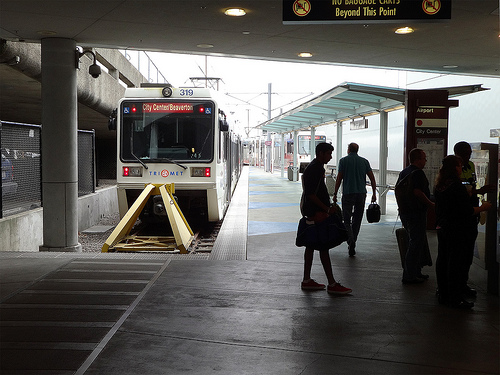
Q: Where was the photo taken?
A: It was taken at the airport.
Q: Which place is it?
A: It is an airport.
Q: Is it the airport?
A: Yes, it is the airport.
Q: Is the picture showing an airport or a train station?
A: It is showing an airport.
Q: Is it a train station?
A: No, it is an airport.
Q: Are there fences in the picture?
A: Yes, there is a fence.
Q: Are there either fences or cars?
A: Yes, there is a fence.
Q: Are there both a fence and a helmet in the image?
A: No, there is a fence but no helmets.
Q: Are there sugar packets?
A: No, there are no sugar packets.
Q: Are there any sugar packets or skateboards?
A: No, there are no sugar packets or skateboards.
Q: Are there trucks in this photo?
A: No, there are no trucks.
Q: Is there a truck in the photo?
A: No, there are no trucks.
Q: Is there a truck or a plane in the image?
A: No, there are no trucks or airplanes.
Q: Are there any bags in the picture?
A: Yes, there is a bag.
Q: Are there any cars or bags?
A: Yes, there is a bag.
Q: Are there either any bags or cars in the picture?
A: Yes, there is a bag.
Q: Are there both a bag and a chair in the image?
A: No, there is a bag but no chairs.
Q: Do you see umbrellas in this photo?
A: No, there are no umbrellas.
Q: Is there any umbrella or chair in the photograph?
A: No, there are no umbrellas or chairs.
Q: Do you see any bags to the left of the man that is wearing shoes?
A: Yes, there is a bag to the left of the man.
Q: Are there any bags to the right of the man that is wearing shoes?
A: No, the bag is to the left of the man.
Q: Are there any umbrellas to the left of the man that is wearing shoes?
A: No, there is a bag to the left of the man.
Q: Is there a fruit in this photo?
A: No, there are no fruits.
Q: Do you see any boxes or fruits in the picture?
A: No, there are no fruits or boxes.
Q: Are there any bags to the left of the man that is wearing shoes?
A: Yes, there are bags to the left of the man.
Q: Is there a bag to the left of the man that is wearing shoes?
A: Yes, there are bags to the left of the man.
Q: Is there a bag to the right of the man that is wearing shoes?
A: No, the bags are to the left of the man.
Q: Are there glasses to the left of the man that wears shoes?
A: No, there are bags to the left of the man.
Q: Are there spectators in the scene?
A: No, there are no spectators.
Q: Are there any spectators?
A: No, there are no spectators.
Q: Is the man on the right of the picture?
A: Yes, the man is on the right of the image.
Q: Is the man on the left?
A: No, the man is on the right of the image.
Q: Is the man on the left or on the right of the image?
A: The man is on the right of the image.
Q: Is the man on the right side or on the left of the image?
A: The man is on the right of the image.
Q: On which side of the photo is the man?
A: The man is on the right of the image.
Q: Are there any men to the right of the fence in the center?
A: Yes, there is a man to the right of the fence.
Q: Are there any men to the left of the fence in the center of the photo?
A: No, the man is to the right of the fence.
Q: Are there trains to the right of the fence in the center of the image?
A: No, there is a man to the right of the fence.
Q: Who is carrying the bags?
A: The man is carrying the bags.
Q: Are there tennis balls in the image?
A: No, there are no tennis balls.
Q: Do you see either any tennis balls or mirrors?
A: No, there are no tennis balls or mirrors.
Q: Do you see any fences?
A: Yes, there is a fence.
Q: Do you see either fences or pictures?
A: Yes, there is a fence.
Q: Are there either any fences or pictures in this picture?
A: Yes, there is a fence.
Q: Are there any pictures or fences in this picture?
A: Yes, there is a fence.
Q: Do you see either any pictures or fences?
A: Yes, there is a fence.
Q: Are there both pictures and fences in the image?
A: No, there is a fence but no pictures.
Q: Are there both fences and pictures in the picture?
A: No, there is a fence but no pictures.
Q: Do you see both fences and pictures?
A: No, there is a fence but no pictures.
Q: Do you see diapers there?
A: No, there are no diapers.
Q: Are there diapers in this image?
A: No, there are no diapers.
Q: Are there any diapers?
A: No, there are no diapers.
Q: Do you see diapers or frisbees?
A: No, there are no diapers or frisbees.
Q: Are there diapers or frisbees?
A: No, there are no diapers or frisbees.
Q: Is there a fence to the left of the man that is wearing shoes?
A: Yes, there is a fence to the left of the man.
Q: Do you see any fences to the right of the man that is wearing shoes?
A: No, the fence is to the left of the man.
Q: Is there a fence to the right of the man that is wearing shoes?
A: No, the fence is to the left of the man.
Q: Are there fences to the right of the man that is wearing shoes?
A: No, the fence is to the left of the man.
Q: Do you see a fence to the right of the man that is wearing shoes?
A: No, the fence is to the left of the man.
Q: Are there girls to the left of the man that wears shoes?
A: No, there is a fence to the left of the man.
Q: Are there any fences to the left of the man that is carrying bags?
A: Yes, there is a fence to the left of the man.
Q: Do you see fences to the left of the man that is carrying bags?
A: Yes, there is a fence to the left of the man.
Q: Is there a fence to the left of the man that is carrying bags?
A: Yes, there is a fence to the left of the man.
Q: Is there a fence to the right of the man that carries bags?
A: No, the fence is to the left of the man.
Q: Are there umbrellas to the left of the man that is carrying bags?
A: No, there is a fence to the left of the man.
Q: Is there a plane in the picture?
A: No, there are no airplanes.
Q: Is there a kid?
A: No, there are no children.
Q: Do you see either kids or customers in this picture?
A: No, there are no kids or customers.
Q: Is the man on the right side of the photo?
A: Yes, the man is on the right of the image.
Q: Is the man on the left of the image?
A: No, the man is on the right of the image.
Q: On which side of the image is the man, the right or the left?
A: The man is on the right of the image.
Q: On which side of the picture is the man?
A: The man is on the right of the image.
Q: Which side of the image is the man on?
A: The man is on the right of the image.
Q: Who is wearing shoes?
A: The man is wearing shoes.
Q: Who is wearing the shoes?
A: The man is wearing shoes.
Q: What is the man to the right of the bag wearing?
A: The man is wearing shoes.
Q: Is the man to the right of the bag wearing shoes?
A: Yes, the man is wearing shoes.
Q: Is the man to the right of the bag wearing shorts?
A: No, the man is wearing shoes.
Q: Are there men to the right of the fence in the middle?
A: Yes, there is a man to the right of the fence.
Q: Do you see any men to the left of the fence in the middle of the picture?
A: No, the man is to the right of the fence.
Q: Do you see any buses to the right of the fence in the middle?
A: No, there is a man to the right of the fence.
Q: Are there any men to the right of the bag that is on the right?
A: Yes, there is a man to the right of the bag.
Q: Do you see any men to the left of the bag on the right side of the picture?
A: No, the man is to the right of the bag.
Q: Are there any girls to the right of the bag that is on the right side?
A: No, there is a man to the right of the bag.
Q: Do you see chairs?
A: No, there are no chairs.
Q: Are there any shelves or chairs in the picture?
A: No, there are no chairs or shelves.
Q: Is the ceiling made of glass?
A: Yes, the ceiling is made of glass.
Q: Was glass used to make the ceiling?
A: Yes, the ceiling is made of glass.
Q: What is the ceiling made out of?
A: The ceiling is made of glass.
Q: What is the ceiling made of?
A: The ceiling is made of glass.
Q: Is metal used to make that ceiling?
A: No, the ceiling is made of glass.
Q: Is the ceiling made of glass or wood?
A: The ceiling is made of glass.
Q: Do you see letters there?
A: Yes, there are letters.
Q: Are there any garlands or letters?
A: Yes, there are letters.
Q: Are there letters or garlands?
A: Yes, there are letters.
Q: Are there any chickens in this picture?
A: No, there are no chickens.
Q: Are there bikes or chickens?
A: No, there are no chickens or bikes.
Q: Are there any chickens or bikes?
A: No, there are no chickens or bikes.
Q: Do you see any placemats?
A: No, there are no placemats.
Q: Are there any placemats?
A: No, there are no placemats.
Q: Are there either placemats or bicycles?
A: No, there are no placemats or bicycles.